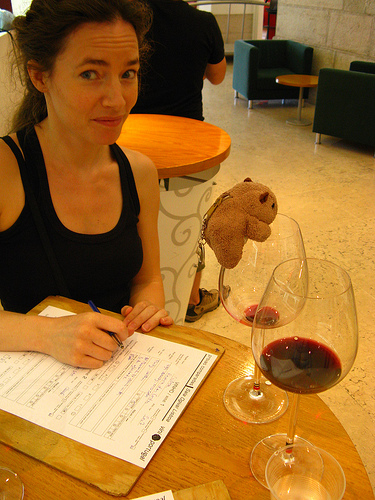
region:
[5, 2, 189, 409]
woman at the table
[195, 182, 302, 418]
glass with stuffed animal on it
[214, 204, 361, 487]
glasses on the table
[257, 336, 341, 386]
liquid inside one of glasses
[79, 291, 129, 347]
pen in woman's hand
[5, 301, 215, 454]
paper woman is writing on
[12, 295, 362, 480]
round table with glasses on it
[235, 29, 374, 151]
table and chairs to side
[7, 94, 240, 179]
round table behind the woman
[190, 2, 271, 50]
railing by table and chairs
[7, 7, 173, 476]
a woman sitting at a table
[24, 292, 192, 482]
she is filling out a form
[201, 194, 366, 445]
two glasses of wine are at the table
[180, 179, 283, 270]
a key chain decoration is on one of the wine glasses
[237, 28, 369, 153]
two sitting chairs are on the other side of the room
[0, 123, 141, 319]
the woman is wearing a black tank top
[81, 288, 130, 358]
the woman is holding a pen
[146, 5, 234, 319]
a man is standing behind the woman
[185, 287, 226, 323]
the mans tennis shoe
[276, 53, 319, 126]
a small table between the chairs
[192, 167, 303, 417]
Teddy bear keychain on wine glass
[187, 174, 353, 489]
Two wine glasses on a table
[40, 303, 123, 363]
Pen in a woman's hand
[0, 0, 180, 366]
Woman wearing a black tank top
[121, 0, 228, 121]
Man wearing a black shirt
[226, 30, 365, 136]
Two green chairs and a table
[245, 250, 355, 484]
Red wine in the wine glass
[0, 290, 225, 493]
Form on brown board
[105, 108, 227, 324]
Scroll paint job on legs of table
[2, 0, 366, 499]
Woman sitting at a round table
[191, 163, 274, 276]
small stuffed animal on wine glass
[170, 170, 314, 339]
stuffed animal on wine glass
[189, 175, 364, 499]
two wine glasses on table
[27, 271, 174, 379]
woman holding a pen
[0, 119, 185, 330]
woman wearing a black tank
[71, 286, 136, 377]
woman holding a blue pen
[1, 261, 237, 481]
woman filling out a form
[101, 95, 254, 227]
round wood table in back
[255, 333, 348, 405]
red wine in glasss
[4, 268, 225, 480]
form with writing on it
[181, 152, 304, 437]
Small keychain teddybear holding on to wineglass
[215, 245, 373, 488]
Wine glass with small amount of wine i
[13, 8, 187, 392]
Woman filling out an application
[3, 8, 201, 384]
Woman with a questioning look on her face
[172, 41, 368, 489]
Two wine glasses next to each other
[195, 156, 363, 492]
Two wine glasses and a plastic cup on a table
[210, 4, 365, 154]
Two blue chairs and a small wooden table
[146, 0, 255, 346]
Man standing in front of a table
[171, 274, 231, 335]
Man's gray athletic shoes